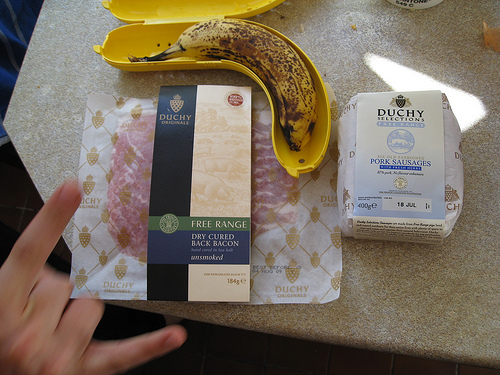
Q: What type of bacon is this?
A: Free range, dry cured.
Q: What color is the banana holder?
A: Yellow.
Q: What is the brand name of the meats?
A: Duchy.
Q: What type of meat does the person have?
A: Bacon and pork sausages.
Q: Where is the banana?
A: In banana holder.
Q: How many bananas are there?
A: 1.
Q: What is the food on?
A: Table.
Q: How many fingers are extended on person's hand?
A: 2.